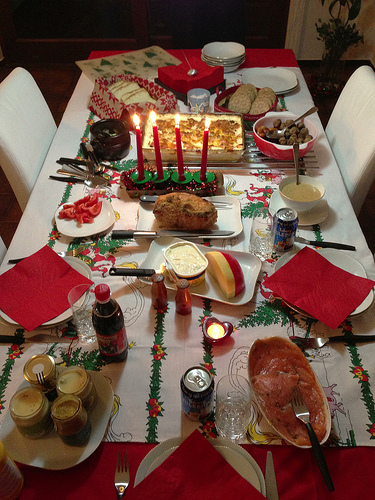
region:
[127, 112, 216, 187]
four red burning candles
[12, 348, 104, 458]
four jars sitting on a plate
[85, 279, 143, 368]
a bottle of cola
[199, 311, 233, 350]
heart shaped candle holder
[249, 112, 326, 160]
red bowl full of food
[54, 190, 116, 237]
sliced tomatoes sitting on a plate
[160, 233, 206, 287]
an open tub of butter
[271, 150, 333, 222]
a bowl of creamy soup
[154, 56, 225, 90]
a pile of red napkins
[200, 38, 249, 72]
a stack of bowls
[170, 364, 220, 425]
aluminum can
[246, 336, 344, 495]
fork sitting in a bowl of food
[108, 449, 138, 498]
shiny silver fork sitting on table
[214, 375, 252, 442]
clear glass sitting on table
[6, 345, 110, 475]
plate holding four jars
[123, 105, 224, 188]
four tall lit candles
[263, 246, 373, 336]
red napkin sitting on a plate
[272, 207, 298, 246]
unopened aluminum can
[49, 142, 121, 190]
a pile of different utensils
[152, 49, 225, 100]
a stack of red napkins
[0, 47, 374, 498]
a table with a meal on it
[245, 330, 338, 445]
red sauce in a white bowl with a fork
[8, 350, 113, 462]
a white plate with four jars on it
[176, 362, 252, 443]
a blue soda can with a glass next to it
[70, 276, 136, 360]
a red soda bottle with a glass next to it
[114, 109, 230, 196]
four red, lit candles in the center of the table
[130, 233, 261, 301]
cheese and spread on a white, rectangular plate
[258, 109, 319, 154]
a circular bowl with meatballs and a fork in it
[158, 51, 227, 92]
a pile of red napkins at the end of the table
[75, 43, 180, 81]
a clear place mat with green Christmas trees on it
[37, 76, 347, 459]
A table set with Christmas dinner.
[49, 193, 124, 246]
A plate with sliced tomatoes.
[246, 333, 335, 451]
A plate with mashed sweet potatoes.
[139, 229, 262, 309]
A tray with cheese and spread.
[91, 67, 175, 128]
Container with slices of bread.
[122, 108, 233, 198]
A four candle center piece.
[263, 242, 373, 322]
A red napkin on white plate.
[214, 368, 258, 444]
Empty glass sitting on table.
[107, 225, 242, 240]
Black handle carving knife next to meat.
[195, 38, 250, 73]
Five white bowls stacked on edge of table.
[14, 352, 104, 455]
a group of scented candles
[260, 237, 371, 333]
the red napkin on the right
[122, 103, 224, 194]
four lit candles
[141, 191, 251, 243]
the main course of the dinner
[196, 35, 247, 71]
a stack of plates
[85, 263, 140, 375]
a bottle of soda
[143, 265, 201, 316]
a salt and pepper shaker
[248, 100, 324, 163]
a bowl of meatballs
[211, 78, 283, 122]
a plate full of cookies